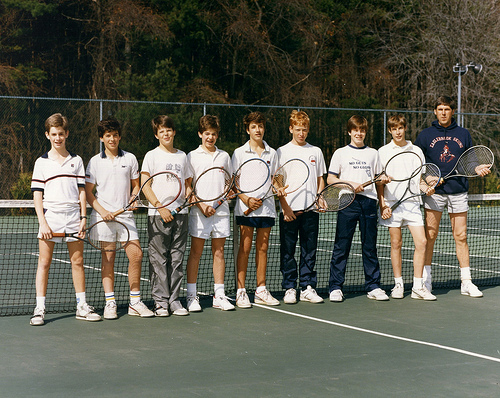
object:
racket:
[51, 220, 129, 252]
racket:
[160, 166, 232, 223]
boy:
[188, 114, 237, 313]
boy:
[277, 109, 328, 303]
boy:
[326, 115, 393, 301]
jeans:
[279, 210, 320, 290]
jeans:
[328, 194, 381, 292]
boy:
[30, 112, 102, 326]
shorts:
[36, 209, 81, 243]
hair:
[434, 96, 456, 110]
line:
[30, 252, 500, 362]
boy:
[231, 112, 290, 308]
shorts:
[188, 215, 230, 239]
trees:
[2, 3, 495, 196]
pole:
[99, 100, 102, 153]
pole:
[203, 105, 206, 116]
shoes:
[169, 300, 188, 315]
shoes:
[103, 302, 118, 319]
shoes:
[153, 302, 170, 316]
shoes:
[128, 301, 155, 318]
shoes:
[212, 296, 235, 311]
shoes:
[187, 296, 202, 312]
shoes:
[283, 288, 298, 304]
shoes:
[235, 291, 251, 309]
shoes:
[254, 289, 280, 306]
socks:
[105, 292, 116, 304]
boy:
[377, 114, 437, 300]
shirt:
[376, 139, 427, 202]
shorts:
[235, 216, 275, 228]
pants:
[147, 214, 188, 314]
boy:
[141, 115, 197, 316]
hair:
[289, 110, 310, 126]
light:
[473, 64, 483, 75]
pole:
[383, 111, 386, 146]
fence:
[0, 95, 498, 199]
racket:
[113, 171, 181, 216]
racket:
[440, 145, 494, 183]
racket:
[244, 158, 310, 216]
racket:
[295, 181, 357, 216]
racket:
[361, 151, 423, 188]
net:
[0, 193, 499, 317]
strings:
[2, 206, 499, 315]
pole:
[457, 71, 462, 127]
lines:
[316, 248, 500, 274]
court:
[0, 212, 499, 397]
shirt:
[30, 150, 86, 213]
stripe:
[31, 174, 86, 184]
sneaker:
[411, 286, 437, 300]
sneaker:
[461, 283, 484, 298]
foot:
[30, 308, 47, 326]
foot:
[76, 308, 102, 321]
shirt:
[231, 140, 279, 219]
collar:
[244, 140, 271, 153]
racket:
[382, 163, 442, 220]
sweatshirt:
[414, 117, 480, 194]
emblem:
[439, 142, 456, 163]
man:
[415, 96, 492, 298]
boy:
[85, 118, 156, 320]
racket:
[204, 158, 270, 218]